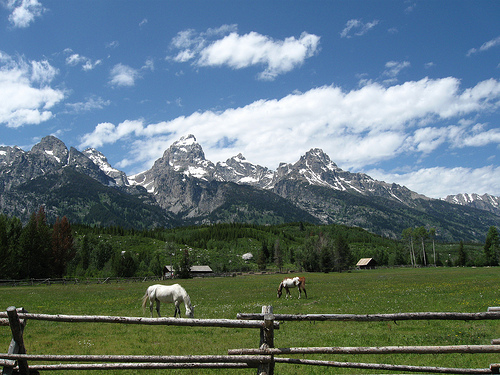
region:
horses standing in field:
[117, 262, 322, 317]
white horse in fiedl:
[125, 278, 202, 326]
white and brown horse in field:
[272, 268, 314, 299]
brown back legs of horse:
[295, 266, 309, 306]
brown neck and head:
[271, 276, 283, 301]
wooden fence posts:
[262, 309, 479, 349]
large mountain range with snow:
[1, 118, 273, 208]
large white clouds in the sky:
[244, 23, 442, 148]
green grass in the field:
[331, 262, 458, 300]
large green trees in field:
[11, 212, 95, 272]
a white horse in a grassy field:
[136, 279, 201, 323]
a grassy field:
[342, 273, 498, 309]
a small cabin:
[353, 254, 378, 272]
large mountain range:
[131, 127, 499, 245]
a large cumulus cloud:
[193, 22, 321, 84]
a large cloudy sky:
[3, 2, 498, 139]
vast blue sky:
[423, 5, 499, 28]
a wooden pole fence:
[1, 300, 499, 370]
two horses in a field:
[137, 268, 332, 318]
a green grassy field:
[338, 274, 481, 306]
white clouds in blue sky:
[25, 15, 76, 46]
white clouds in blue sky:
[200, 72, 227, 99]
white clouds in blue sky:
[347, 49, 411, 80]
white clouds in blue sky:
[265, 26, 313, 90]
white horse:
[140, 268, 202, 319]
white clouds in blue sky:
[45, 28, 136, 86]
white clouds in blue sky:
[65, 9, 107, 47]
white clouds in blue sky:
[310, 72, 364, 117]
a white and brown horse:
[266, 261, 326, 314]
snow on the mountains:
[33, 125, 388, 207]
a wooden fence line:
[6, 293, 497, 374]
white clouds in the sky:
[26, 17, 473, 182]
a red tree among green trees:
[39, 203, 94, 290]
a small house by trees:
[356, 252, 387, 285]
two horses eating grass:
[93, 250, 352, 361]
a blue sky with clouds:
[21, 7, 498, 219]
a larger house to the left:
[150, 254, 224, 289]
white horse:
[132, 286, 210, 320]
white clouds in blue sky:
[41, 31, 95, 81]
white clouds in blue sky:
[352, 58, 390, 92]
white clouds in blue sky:
[407, 89, 454, 134]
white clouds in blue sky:
[308, 59, 360, 110]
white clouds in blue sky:
[145, 29, 213, 94]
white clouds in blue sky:
[282, 35, 323, 86]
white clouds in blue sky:
[124, 59, 194, 111]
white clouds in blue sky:
[261, 86, 336, 138]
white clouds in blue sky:
[404, 11, 446, 95]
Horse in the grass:
[266, 274, 314, 303]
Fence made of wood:
[260, 308, 432, 374]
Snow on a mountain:
[156, 133, 215, 185]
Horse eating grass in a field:
[136, 280, 194, 318]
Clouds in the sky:
[347, 140, 390, 165]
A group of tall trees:
[392, 224, 443, 276]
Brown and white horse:
[273, 277, 311, 304]